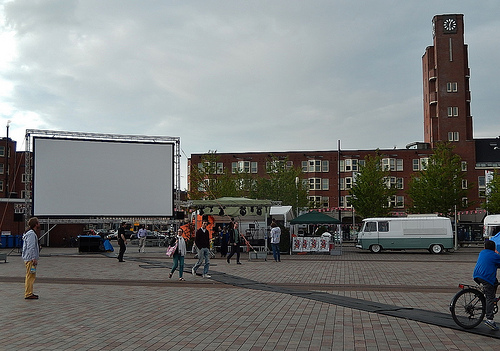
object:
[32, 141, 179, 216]
screen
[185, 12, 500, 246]
building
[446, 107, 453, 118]
window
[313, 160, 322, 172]
window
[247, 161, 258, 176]
window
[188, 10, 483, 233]
tower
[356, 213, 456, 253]
van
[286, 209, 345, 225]
tent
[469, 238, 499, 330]
boy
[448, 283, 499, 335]
bicycle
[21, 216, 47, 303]
man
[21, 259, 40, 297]
pants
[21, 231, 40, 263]
shirt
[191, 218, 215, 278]
man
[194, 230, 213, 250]
sweater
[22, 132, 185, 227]
billboard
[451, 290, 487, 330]
spokes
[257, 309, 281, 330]
tile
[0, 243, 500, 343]
ground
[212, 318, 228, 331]
tile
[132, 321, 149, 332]
tile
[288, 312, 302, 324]
line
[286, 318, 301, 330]
tile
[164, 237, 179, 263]
bag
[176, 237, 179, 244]
shoulder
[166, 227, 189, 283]
woman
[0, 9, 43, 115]
cloud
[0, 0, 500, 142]
sky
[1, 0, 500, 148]
cloud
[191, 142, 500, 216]
cluster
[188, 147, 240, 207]
trees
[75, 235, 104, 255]
table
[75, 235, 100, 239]
top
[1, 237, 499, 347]
street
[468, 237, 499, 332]
person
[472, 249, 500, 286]
jacket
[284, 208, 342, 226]
awning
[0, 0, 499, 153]
background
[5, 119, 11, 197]
smokestack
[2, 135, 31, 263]
building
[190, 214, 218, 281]
person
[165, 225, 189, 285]
person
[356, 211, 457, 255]
bus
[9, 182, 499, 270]
center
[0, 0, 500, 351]
town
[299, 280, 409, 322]
mat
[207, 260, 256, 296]
mat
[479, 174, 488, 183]
window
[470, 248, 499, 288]
blue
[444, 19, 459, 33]
clock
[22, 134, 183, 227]
frame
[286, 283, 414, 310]
cables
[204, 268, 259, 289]
cables